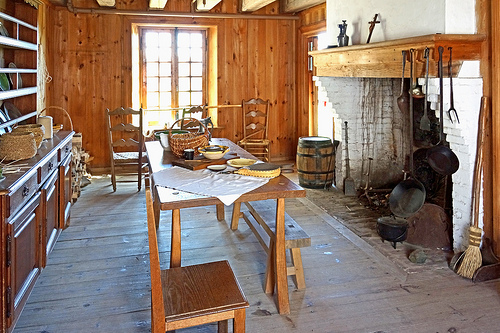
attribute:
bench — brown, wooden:
[229, 200, 307, 296]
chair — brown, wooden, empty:
[107, 101, 151, 195]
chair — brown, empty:
[145, 173, 251, 333]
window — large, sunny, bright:
[140, 27, 208, 123]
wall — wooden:
[53, 5, 300, 173]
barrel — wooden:
[296, 137, 336, 190]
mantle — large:
[307, 31, 483, 80]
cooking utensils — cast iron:
[390, 47, 454, 217]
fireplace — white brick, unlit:
[316, 76, 457, 245]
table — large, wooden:
[143, 135, 305, 318]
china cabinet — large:
[1, 2, 76, 331]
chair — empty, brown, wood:
[239, 95, 272, 167]